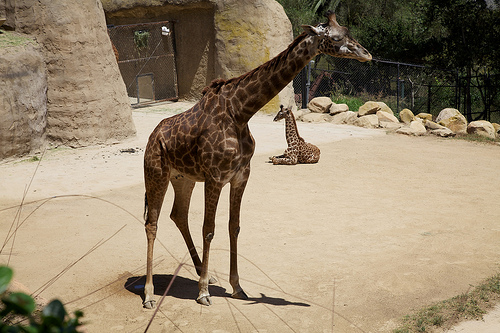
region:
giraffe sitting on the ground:
[271, 104, 328, 175]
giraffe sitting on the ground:
[261, 94, 342, 199]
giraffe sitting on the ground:
[247, 86, 309, 181]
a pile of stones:
[304, 87, 494, 142]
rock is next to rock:
[305, 95, 332, 112]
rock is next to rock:
[328, 102, 345, 112]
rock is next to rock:
[358, 98, 389, 113]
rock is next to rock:
[371, 106, 393, 126]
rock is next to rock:
[398, 107, 414, 127]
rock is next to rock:
[417, 110, 433, 120]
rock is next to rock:
[435, 105, 465, 130]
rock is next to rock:
[467, 117, 497, 140]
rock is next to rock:
[397, 121, 423, 131]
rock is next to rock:
[380, 116, 401, 133]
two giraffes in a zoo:
[122, 11, 402, 311]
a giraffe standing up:
[133, 6, 385, 318]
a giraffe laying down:
[270, 103, 327, 173]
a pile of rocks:
[312, 84, 472, 143]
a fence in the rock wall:
[101, 17, 199, 117]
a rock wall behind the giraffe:
[4, 5, 289, 143]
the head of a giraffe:
[295, 8, 380, 66]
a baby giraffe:
[271, 97, 322, 176]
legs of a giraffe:
[126, 163, 262, 312]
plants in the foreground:
[6, 165, 131, 332]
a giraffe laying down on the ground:
[274, 106, 321, 165]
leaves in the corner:
[1, 264, 86, 329]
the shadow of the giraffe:
[123, 271, 312, 316]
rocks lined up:
[312, 93, 492, 146]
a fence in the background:
[322, 52, 499, 121]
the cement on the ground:
[273, 170, 481, 285]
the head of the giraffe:
[303, 16, 372, 58]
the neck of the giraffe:
[223, 37, 321, 117]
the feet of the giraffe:
[138, 284, 250, 309]